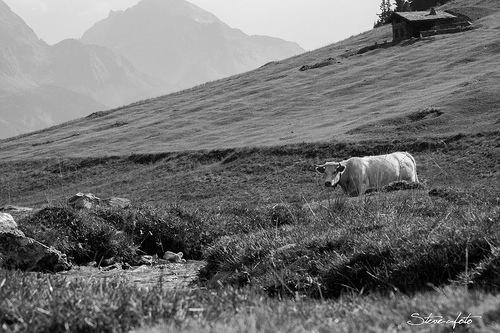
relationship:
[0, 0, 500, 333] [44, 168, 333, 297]
grass on ground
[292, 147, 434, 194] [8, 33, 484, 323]
cow walking in grass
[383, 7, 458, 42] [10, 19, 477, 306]
cabin on grass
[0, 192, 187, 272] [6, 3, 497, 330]
rock on pasture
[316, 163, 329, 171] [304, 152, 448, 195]
ear of cow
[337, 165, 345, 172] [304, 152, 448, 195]
cow's ears of cow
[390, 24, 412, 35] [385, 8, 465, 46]
windows on side of house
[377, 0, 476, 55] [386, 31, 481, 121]
cabin on hill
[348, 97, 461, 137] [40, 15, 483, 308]
crater in ground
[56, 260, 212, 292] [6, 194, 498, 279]
water between bank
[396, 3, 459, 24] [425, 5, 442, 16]
roof with chimney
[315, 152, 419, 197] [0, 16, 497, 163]
cow on slope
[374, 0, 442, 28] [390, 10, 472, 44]
trees by cabin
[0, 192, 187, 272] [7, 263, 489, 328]
rock on ground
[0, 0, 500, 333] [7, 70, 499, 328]
grass on ground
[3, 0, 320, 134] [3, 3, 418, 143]
mountains in background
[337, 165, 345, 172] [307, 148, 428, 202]
cow's ears on cow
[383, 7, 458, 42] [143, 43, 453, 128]
cabin on hill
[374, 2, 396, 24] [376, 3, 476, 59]
trees by cottage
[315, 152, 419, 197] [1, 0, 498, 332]
cow in grass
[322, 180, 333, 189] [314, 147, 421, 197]
muzzle on cow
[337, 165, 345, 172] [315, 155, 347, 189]
cow's ears on head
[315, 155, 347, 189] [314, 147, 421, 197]
head on cow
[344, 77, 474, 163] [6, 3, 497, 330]
pit in pasture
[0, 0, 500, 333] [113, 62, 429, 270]
pasture on a hill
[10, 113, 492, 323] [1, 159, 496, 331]
field of grass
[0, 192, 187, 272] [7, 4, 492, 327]
rock on ground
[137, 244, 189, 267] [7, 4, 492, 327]
rock on ground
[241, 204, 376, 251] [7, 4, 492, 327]
grass on ground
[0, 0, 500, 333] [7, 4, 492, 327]
grass on ground